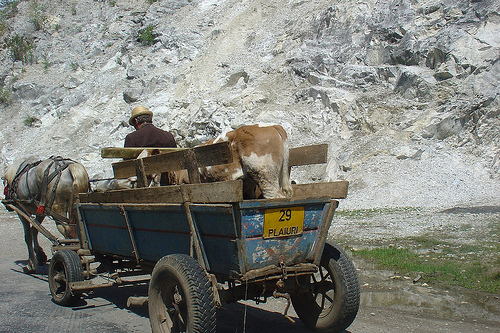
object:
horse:
[6, 153, 88, 271]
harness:
[6, 156, 86, 191]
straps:
[42, 155, 67, 180]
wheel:
[144, 250, 215, 332]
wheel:
[46, 246, 86, 304]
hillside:
[2, 1, 499, 199]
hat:
[124, 108, 162, 126]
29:
[279, 210, 290, 225]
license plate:
[261, 207, 303, 236]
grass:
[350, 235, 498, 297]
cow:
[194, 112, 299, 193]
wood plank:
[113, 142, 234, 179]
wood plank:
[73, 177, 243, 205]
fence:
[99, 142, 349, 201]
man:
[122, 105, 174, 149]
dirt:
[369, 288, 498, 331]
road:
[1, 206, 499, 330]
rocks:
[119, 68, 149, 102]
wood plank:
[282, 139, 332, 166]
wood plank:
[286, 180, 351, 199]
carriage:
[50, 140, 362, 327]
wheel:
[282, 242, 360, 329]